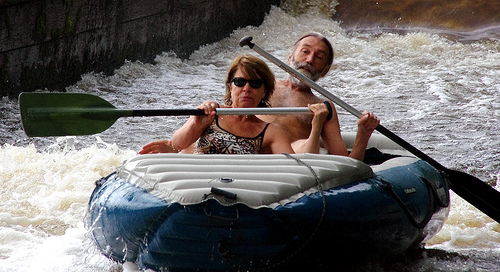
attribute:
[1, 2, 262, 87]
wall — stone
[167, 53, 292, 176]
tank top — woman's, bathing, suit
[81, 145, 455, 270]
raft — blue, white, inflated 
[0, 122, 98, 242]
splash — water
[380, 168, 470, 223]
handles — side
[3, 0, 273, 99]
block — large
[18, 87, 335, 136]
oar — green 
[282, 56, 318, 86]
mustache — man's, white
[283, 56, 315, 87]
beard — white, man's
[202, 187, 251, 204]
pill tie — pull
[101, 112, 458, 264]
boat — blow up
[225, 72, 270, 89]
sunglasses — black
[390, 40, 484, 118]
water — rapid , foamy 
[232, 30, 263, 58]
knob — black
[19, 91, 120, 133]
paddle — green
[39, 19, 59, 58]
moss — green 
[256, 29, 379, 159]
man — light 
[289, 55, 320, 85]
beard — gray 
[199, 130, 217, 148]
design — white , black 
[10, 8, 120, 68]
wall — concrete 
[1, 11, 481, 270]
waters — rapid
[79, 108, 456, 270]
raft — blue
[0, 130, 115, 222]
froth — white